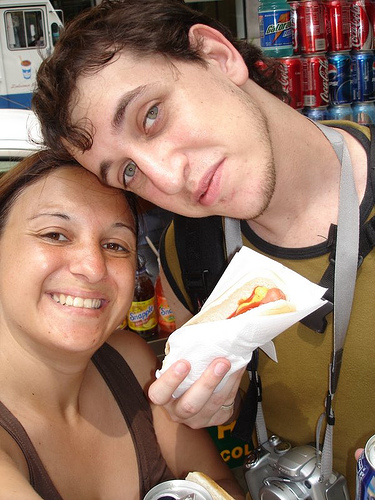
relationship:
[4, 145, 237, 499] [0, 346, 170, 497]
woman has brown shirt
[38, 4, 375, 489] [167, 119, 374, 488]
man in shirt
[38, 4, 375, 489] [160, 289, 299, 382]
man holding hotdog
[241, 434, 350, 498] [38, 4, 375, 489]
camera on man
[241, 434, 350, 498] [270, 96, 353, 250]
camera on man's neck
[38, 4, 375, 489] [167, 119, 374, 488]
man wears yellow shirt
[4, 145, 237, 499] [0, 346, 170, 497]
woman wears brown shirt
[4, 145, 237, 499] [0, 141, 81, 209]
woman has hair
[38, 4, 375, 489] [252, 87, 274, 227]
man has facial hair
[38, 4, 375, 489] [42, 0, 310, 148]
man has brown hair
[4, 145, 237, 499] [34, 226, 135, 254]
woman has brown eyes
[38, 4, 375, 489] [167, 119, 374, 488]
man has yellow shirt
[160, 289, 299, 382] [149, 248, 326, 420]
hotdog on a napkin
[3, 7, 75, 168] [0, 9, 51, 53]
truck shows side window